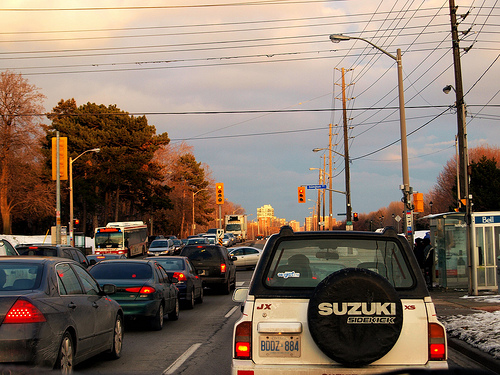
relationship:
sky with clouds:
[0, 6, 498, 198] [3, 6, 155, 51]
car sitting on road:
[228, 225, 450, 375] [114, 282, 230, 371]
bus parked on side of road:
[91, 221, 149, 258] [14, 210, 454, 280]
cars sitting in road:
[2, 244, 231, 361] [4, 252, 494, 374]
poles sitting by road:
[321, 117, 484, 202] [23, 156, 455, 338]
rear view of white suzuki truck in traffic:
[192, 220, 477, 375] [72, 189, 498, 375]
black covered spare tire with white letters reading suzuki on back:
[306, 265, 401, 375] [213, 224, 483, 375]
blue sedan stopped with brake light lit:
[0, 267, 84, 352] [12, 296, 34, 375]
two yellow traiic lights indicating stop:
[202, 173, 315, 230] [180, 158, 310, 283]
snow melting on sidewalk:
[452, 306, 499, 353] [187, 335, 497, 375]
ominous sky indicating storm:
[14, 51, 344, 89] [74, 102, 384, 129]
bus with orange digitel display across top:
[85, 220, 122, 245] [94, 228, 127, 232]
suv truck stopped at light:
[157, 223, 229, 267] [203, 255, 233, 324]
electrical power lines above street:
[4, 51, 488, 148] [56, 168, 329, 375]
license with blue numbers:
[244, 324, 304, 375] [260, 336, 303, 375]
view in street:
[30, 108, 472, 323] [82, 164, 280, 375]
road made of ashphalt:
[80, 259, 217, 375] [98, 307, 214, 375]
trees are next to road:
[4, 101, 240, 228] [75, 190, 255, 375]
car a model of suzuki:
[224, 225, 450, 375] [313, 283, 397, 353]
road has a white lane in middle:
[80, 259, 217, 375] [158, 259, 234, 375]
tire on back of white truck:
[319, 265, 399, 375] [219, 238, 453, 375]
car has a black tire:
[228, 225, 450, 375] [311, 267, 399, 363]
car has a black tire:
[228, 225, 450, 375] [303, 270, 404, 363]